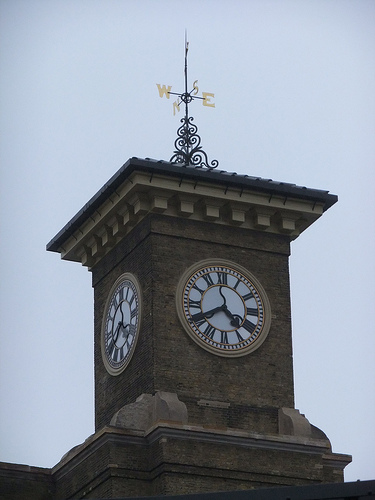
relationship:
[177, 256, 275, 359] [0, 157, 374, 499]
clock on building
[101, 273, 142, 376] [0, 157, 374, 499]
clock on building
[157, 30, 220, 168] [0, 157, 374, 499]
weather vane on building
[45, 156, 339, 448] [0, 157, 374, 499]
clock tower on building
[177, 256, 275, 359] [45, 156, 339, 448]
clock on clock tower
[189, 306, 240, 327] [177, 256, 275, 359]
hands of clock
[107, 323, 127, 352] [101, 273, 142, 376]
hands of clock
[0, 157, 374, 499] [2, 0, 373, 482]
building below sky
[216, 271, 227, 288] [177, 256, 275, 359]
number on clock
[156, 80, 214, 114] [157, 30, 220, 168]
letters on weather vane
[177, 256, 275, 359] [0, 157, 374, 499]
clock on top of building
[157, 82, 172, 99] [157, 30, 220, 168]
w on weather vane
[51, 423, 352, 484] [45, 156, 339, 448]
ledge of clock tower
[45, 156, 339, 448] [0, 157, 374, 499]
clock tower on top of building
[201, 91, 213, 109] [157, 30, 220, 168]
e on weather vane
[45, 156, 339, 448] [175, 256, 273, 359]
clock tower has clock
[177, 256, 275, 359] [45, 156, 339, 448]
clock in clock tower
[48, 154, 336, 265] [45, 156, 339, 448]
decoration on clock tower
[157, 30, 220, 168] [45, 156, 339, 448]
weather vane on top of clock tower